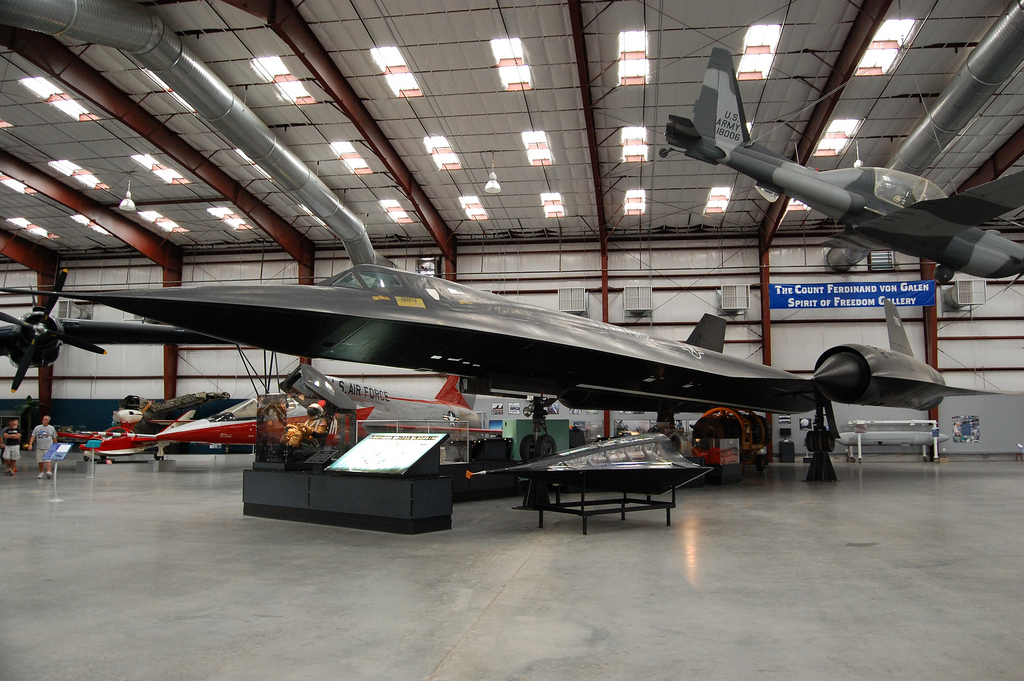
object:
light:
[367, 42, 423, 104]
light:
[419, 130, 467, 170]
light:
[367, 198, 415, 231]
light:
[855, 14, 916, 82]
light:
[823, 116, 848, 160]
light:
[739, 26, 779, 85]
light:
[701, 180, 728, 218]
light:
[13, 74, 101, 119]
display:
[330, 431, 442, 475]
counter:
[234, 420, 454, 526]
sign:
[766, 276, 938, 308]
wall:
[718, 237, 968, 356]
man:
[30, 415, 59, 478]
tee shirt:
[29, 423, 57, 449]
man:
[0, 417, 23, 473]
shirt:
[4, 425, 22, 447]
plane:
[663, 85, 1018, 275]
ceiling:
[0, 2, 1019, 243]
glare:
[675, 508, 705, 600]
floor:
[0, 508, 1019, 654]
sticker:
[396, 294, 429, 309]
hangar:
[3, 12, 1008, 681]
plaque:
[258, 419, 438, 528]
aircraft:
[95, 261, 951, 530]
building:
[32, 7, 1021, 322]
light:
[15, 28, 883, 244]